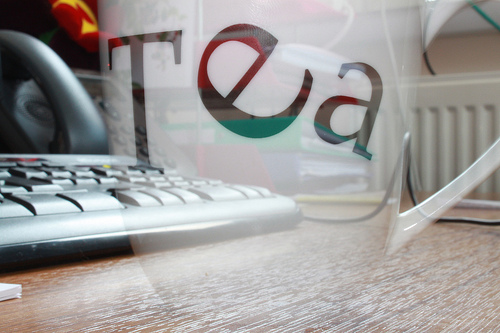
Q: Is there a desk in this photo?
A: Yes, there is a desk.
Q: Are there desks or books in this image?
A: Yes, there is a desk.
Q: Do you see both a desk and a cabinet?
A: No, there is a desk but no cabinets.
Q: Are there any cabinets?
A: No, there are no cabinets.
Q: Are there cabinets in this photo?
A: No, there are no cabinets.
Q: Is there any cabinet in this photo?
A: No, there are no cabinets.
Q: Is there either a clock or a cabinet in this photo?
A: No, there are no cabinets or clocks.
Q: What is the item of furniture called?
A: The piece of furniture is a desk.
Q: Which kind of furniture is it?
A: The piece of furniture is a desk.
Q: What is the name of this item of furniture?
A: This is a desk.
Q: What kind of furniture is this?
A: This is a desk.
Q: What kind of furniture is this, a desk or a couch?
A: This is a desk.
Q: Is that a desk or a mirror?
A: That is a desk.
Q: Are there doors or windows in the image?
A: Yes, there are windows.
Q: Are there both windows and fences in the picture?
A: No, there are windows but no fences.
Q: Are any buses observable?
A: No, there are no buses.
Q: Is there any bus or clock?
A: No, there are no buses or clocks.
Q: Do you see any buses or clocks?
A: No, there are no buses or clocks.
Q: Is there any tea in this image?
A: Yes, there is tea.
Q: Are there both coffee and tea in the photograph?
A: No, there is tea but no coffee.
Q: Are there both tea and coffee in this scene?
A: No, there is tea but no coffee.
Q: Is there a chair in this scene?
A: No, there are no chairs.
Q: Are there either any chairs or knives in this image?
A: No, there are no chairs or knives.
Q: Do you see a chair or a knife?
A: No, there are no chairs or knives.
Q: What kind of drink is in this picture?
A: The drink is tea.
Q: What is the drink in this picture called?
A: The drink is tea.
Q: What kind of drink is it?
A: The drink is tea.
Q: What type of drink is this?
A: This is tea.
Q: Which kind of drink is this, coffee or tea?
A: This is tea.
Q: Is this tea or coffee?
A: This is tea.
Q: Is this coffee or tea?
A: This is tea.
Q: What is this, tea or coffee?
A: This is tea.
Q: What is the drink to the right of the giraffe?
A: The drink is tea.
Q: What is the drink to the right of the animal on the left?
A: The drink is tea.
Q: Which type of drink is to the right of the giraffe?
A: The drink is tea.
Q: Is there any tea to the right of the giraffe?
A: Yes, there is tea to the right of the giraffe.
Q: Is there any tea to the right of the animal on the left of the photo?
A: Yes, there is tea to the right of the giraffe.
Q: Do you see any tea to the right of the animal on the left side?
A: Yes, there is tea to the right of the giraffe.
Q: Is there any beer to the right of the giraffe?
A: No, there is tea to the right of the giraffe.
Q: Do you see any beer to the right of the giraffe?
A: No, there is tea to the right of the giraffe.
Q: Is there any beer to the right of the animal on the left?
A: No, there is tea to the right of the giraffe.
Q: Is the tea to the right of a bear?
A: No, the tea is to the right of the giraffe.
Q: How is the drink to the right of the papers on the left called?
A: The drink is tea.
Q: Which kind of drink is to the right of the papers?
A: The drink is tea.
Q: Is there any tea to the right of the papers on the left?
A: Yes, there is tea to the right of the papers.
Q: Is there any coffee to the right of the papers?
A: No, there is tea to the right of the papers.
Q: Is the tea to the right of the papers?
A: Yes, the tea is to the right of the papers.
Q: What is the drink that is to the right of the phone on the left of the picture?
A: The drink is tea.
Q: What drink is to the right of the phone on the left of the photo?
A: The drink is tea.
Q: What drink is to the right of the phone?
A: The drink is tea.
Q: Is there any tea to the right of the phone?
A: Yes, there is tea to the right of the phone.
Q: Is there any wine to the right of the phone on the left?
A: No, there is tea to the right of the phone.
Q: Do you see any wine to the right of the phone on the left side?
A: No, there is tea to the right of the phone.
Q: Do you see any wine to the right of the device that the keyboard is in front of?
A: No, there is tea to the right of the phone.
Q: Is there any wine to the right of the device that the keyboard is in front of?
A: No, there is tea to the right of the phone.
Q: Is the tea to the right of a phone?
A: Yes, the tea is to the right of a phone.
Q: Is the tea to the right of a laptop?
A: No, the tea is to the right of a phone.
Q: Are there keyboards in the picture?
A: Yes, there is a keyboard.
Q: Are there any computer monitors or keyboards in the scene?
A: Yes, there is a keyboard.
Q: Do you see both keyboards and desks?
A: Yes, there are both a keyboard and a desk.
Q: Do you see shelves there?
A: No, there are no shelves.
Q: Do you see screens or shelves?
A: No, there are no shelves or screens.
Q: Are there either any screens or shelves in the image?
A: No, there are no shelves or screens.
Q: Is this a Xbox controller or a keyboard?
A: This is a keyboard.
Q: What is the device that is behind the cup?
A: The device is a keyboard.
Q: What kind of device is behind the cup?
A: The device is a keyboard.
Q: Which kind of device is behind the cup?
A: The device is a keyboard.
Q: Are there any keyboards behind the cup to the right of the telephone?
A: Yes, there is a keyboard behind the cup.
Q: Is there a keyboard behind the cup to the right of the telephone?
A: Yes, there is a keyboard behind the cup.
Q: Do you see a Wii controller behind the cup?
A: No, there is a keyboard behind the cup.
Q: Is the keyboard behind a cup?
A: Yes, the keyboard is behind a cup.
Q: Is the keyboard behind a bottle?
A: No, the keyboard is behind a cup.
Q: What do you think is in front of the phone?
A: The keyboard is in front of the phone.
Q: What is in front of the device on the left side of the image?
A: The keyboard is in front of the phone.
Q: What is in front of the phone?
A: The keyboard is in front of the phone.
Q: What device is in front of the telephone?
A: The device is a keyboard.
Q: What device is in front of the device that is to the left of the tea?
A: The device is a keyboard.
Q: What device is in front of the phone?
A: The device is a keyboard.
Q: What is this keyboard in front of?
A: The keyboard is in front of the telephone.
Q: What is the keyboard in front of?
A: The keyboard is in front of the telephone.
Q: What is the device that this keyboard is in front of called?
A: The device is a phone.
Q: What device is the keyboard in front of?
A: The keyboard is in front of the telephone.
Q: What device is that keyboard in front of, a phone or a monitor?
A: The keyboard is in front of a phone.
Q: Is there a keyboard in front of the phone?
A: Yes, there is a keyboard in front of the phone.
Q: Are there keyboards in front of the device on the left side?
A: Yes, there is a keyboard in front of the phone.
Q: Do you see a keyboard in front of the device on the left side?
A: Yes, there is a keyboard in front of the phone.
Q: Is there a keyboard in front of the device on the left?
A: Yes, there is a keyboard in front of the phone.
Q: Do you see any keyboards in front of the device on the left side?
A: Yes, there is a keyboard in front of the phone.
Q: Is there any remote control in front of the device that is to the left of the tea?
A: No, there is a keyboard in front of the telephone.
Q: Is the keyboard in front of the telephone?
A: Yes, the keyboard is in front of the telephone.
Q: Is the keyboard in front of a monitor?
A: No, the keyboard is in front of the telephone.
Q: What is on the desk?
A: The keyboard is on the desk.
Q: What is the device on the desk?
A: The device is a keyboard.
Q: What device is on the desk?
A: The device is a keyboard.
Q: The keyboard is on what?
A: The keyboard is on the desk.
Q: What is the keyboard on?
A: The keyboard is on the desk.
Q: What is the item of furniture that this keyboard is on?
A: The piece of furniture is a desk.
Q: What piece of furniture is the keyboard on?
A: The keyboard is on the desk.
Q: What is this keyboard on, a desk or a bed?
A: The keyboard is on a desk.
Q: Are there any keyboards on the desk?
A: Yes, there is a keyboard on the desk.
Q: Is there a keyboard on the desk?
A: Yes, there is a keyboard on the desk.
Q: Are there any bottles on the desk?
A: No, there is a keyboard on the desk.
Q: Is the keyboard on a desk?
A: Yes, the keyboard is on a desk.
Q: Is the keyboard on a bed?
A: No, the keyboard is on a desk.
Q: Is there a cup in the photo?
A: Yes, there is a cup.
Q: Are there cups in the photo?
A: Yes, there is a cup.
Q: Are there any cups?
A: Yes, there is a cup.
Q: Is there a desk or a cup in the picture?
A: Yes, there is a cup.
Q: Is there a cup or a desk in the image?
A: Yes, there is a cup.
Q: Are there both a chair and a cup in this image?
A: No, there is a cup but no chairs.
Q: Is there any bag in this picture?
A: No, there are no bags.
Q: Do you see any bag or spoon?
A: No, there are no bags or spoons.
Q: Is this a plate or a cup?
A: This is a cup.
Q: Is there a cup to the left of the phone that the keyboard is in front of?
A: No, the cup is to the right of the phone.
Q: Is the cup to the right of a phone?
A: Yes, the cup is to the right of a phone.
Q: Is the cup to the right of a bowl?
A: No, the cup is to the right of a phone.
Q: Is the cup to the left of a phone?
A: No, the cup is to the right of a phone.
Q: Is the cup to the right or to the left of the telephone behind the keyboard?
A: The cup is to the right of the phone.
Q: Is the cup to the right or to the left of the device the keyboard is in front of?
A: The cup is to the right of the phone.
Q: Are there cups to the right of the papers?
A: Yes, there is a cup to the right of the papers.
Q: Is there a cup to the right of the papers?
A: Yes, there is a cup to the right of the papers.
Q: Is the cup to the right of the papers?
A: Yes, the cup is to the right of the papers.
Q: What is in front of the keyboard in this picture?
A: The cup is in front of the keyboard.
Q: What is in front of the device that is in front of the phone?
A: The cup is in front of the keyboard.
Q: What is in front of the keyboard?
A: The cup is in front of the keyboard.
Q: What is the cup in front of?
A: The cup is in front of the keyboard.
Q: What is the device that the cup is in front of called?
A: The device is a keyboard.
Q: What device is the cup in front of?
A: The cup is in front of the keyboard.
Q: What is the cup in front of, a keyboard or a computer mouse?
A: The cup is in front of a keyboard.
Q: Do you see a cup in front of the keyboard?
A: Yes, there is a cup in front of the keyboard.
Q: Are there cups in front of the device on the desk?
A: Yes, there is a cup in front of the keyboard.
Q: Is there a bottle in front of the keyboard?
A: No, there is a cup in front of the keyboard.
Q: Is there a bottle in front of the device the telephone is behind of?
A: No, there is a cup in front of the keyboard.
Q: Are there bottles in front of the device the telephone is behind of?
A: No, there is a cup in front of the keyboard.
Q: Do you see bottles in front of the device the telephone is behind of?
A: No, there is a cup in front of the keyboard.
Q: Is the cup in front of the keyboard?
A: Yes, the cup is in front of the keyboard.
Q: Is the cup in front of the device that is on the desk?
A: Yes, the cup is in front of the keyboard.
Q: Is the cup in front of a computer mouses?
A: No, the cup is in front of the keyboard.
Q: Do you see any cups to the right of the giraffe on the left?
A: Yes, there is a cup to the right of the giraffe.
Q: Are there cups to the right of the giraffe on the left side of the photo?
A: Yes, there is a cup to the right of the giraffe.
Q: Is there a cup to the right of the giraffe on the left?
A: Yes, there is a cup to the right of the giraffe.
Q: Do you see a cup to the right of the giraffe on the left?
A: Yes, there is a cup to the right of the giraffe.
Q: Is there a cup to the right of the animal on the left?
A: Yes, there is a cup to the right of the giraffe.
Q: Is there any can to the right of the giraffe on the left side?
A: No, there is a cup to the right of the giraffe.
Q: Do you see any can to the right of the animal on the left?
A: No, there is a cup to the right of the giraffe.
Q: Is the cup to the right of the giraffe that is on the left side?
A: Yes, the cup is to the right of the giraffe.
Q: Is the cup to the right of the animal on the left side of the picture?
A: Yes, the cup is to the right of the giraffe.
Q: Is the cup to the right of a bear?
A: No, the cup is to the right of the giraffe.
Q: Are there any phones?
A: Yes, there is a phone.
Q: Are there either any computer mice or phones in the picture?
A: Yes, there is a phone.